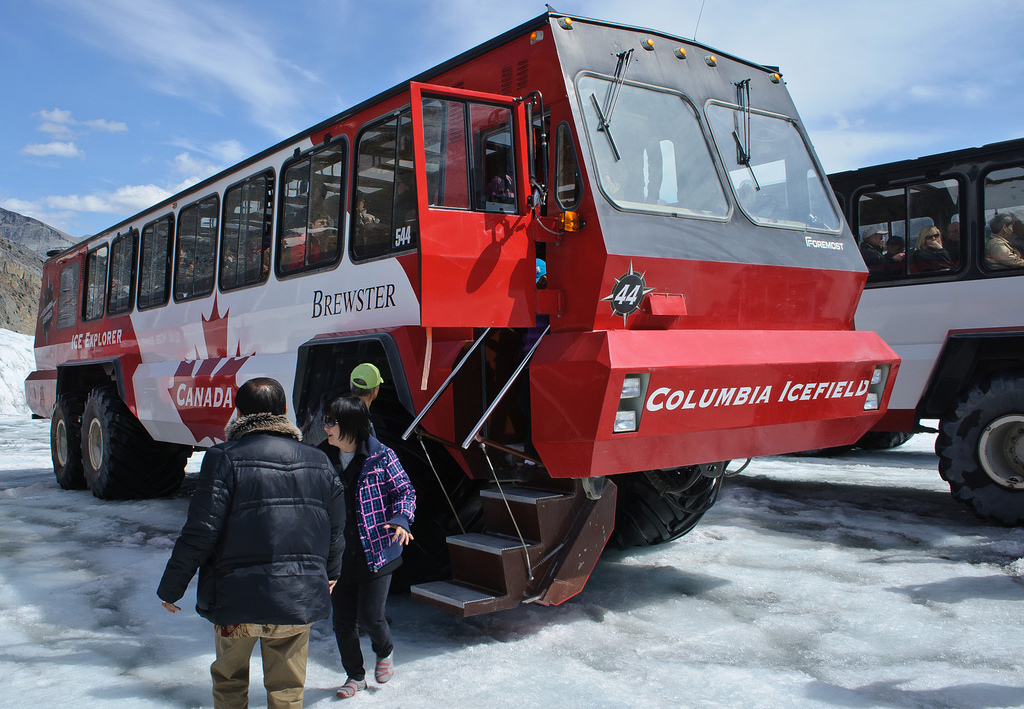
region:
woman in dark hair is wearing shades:
[318, 392, 354, 443]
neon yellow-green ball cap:
[334, 351, 395, 399]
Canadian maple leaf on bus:
[167, 300, 272, 466]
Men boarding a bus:
[209, 355, 470, 706]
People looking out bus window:
[860, 213, 1016, 252]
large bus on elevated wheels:
[60, 96, 889, 575]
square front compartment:
[540, 9, 930, 291]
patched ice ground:
[571, 480, 867, 690]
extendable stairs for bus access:
[394, 325, 704, 705]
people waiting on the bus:
[101, 203, 428, 274]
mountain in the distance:
[5, 205, 81, 466]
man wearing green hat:
[344, 357, 396, 433]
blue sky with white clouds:
[47, 42, 209, 167]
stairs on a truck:
[417, 446, 626, 678]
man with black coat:
[180, 349, 336, 657]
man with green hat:
[348, 354, 393, 419]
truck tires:
[37, 375, 151, 503]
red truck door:
[363, 76, 556, 349]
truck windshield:
[549, 16, 860, 273]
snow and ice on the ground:
[696, 557, 900, 688]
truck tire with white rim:
[902, 317, 1016, 559]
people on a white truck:
[863, 172, 959, 305]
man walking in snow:
[152, 374, 355, 706]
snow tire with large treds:
[933, 370, 1022, 525]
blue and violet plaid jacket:
[310, 435, 419, 576]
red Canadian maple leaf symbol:
[164, 286, 262, 451]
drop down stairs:
[396, 321, 581, 620]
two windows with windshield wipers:
[571, 45, 847, 235]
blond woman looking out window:
[907, 220, 950, 282]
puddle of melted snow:
[798, 672, 1018, 701]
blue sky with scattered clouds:
[2, 4, 1018, 239]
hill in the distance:
[0, 206, 89, 340]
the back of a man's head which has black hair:
[229, 376, 288, 427]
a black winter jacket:
[168, 417, 343, 624]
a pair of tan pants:
[214, 625, 314, 706]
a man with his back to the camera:
[162, 377, 337, 706]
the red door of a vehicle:
[403, 77, 556, 321]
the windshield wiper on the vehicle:
[576, 35, 654, 157]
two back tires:
[29, 395, 132, 487]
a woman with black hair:
[321, 404, 417, 700]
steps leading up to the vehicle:
[428, 475, 590, 609]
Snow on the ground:
[721, 576, 918, 675]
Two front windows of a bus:
[565, 61, 865, 269]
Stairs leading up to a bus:
[415, 367, 623, 624]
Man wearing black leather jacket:
[167, 398, 350, 628]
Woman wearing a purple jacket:
[302, 379, 420, 566]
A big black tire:
[903, 353, 1016, 499]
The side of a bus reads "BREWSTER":
[290, 256, 438, 341]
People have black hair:
[226, 347, 380, 493]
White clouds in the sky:
[37, 37, 224, 169]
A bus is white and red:
[19, 24, 922, 558]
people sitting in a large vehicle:
[857, 212, 1019, 270]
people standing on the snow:
[142, 342, 450, 707]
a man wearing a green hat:
[340, 358, 386, 397]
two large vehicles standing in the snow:
[104, 78, 1016, 530]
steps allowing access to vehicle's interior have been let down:
[416, 308, 590, 628]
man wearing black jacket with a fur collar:
[186, 418, 339, 625]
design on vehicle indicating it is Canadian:
[133, 282, 255, 450]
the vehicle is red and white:
[262, 131, 572, 403]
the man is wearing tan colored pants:
[202, 631, 329, 707]